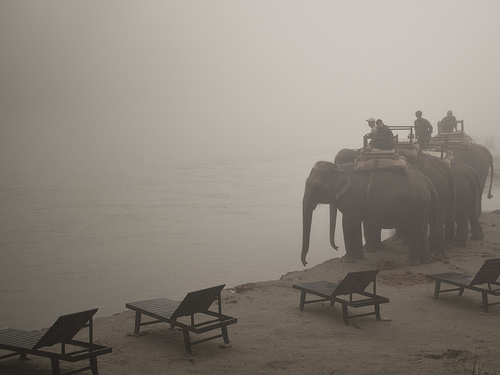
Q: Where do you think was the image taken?
A: It was taken at the beach.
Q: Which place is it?
A: It is a beach.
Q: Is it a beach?
A: Yes, it is a beach.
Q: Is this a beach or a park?
A: It is a beach.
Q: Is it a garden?
A: No, it is a beach.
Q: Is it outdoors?
A: Yes, it is outdoors.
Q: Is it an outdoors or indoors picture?
A: It is outdoors.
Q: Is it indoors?
A: No, it is outdoors.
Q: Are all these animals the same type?
A: Yes, all the animals are elephants.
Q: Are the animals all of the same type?
A: Yes, all the animals are elephants.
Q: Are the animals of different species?
A: No, all the animals are elephants.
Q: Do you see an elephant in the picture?
A: Yes, there is an elephant.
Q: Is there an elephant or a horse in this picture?
A: Yes, there is an elephant.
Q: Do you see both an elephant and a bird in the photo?
A: No, there is an elephant but no birds.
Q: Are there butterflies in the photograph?
A: No, there are no butterflies.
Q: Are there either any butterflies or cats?
A: No, there are no butterflies or cats.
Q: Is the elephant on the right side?
A: Yes, the elephant is on the right of the image.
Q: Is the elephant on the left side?
A: No, the elephant is on the right of the image.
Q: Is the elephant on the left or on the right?
A: The elephant is on the right of the image.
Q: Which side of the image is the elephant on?
A: The elephant is on the right of the image.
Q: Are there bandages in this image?
A: No, there are no bandages.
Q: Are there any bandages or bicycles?
A: No, there are no bandages or bicycles.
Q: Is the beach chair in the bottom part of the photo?
A: Yes, the beach chair is in the bottom of the image.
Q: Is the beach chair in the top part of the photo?
A: No, the beach chair is in the bottom of the image.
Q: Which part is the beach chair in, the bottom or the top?
A: The beach chair is in the bottom of the image.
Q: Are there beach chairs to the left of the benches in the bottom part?
A: Yes, there is a beach chair to the left of the benches.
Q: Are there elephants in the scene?
A: Yes, there is an elephant.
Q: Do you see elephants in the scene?
A: Yes, there is an elephant.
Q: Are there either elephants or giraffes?
A: Yes, there is an elephant.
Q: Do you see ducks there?
A: No, there are no ducks.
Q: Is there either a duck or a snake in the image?
A: No, there are no ducks or snakes.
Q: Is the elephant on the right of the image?
A: Yes, the elephant is on the right of the image.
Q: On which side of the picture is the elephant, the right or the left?
A: The elephant is on the right of the image.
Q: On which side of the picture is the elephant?
A: The elephant is on the right of the image.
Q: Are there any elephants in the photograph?
A: Yes, there is an elephant.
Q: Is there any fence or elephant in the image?
A: Yes, there is an elephant.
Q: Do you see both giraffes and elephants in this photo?
A: No, there is an elephant but no giraffes.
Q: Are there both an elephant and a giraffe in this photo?
A: No, there is an elephant but no giraffes.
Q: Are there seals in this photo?
A: No, there are no seals.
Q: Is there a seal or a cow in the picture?
A: No, there are no seals or cows.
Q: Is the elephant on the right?
A: Yes, the elephant is on the right of the image.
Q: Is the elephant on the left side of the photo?
A: No, the elephant is on the right of the image.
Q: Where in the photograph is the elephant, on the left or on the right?
A: The elephant is on the right of the image.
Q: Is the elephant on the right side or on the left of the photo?
A: The elephant is on the right of the image.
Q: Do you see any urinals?
A: No, there are no urinals.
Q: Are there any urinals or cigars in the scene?
A: No, there are no urinals or cigars.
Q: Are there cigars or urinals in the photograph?
A: No, there are no urinals or cigars.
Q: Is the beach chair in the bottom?
A: Yes, the beach chair is in the bottom of the image.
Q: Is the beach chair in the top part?
A: No, the beach chair is in the bottom of the image.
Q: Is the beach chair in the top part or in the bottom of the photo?
A: The beach chair is in the bottom of the image.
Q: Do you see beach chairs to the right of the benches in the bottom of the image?
A: Yes, there is a beach chair to the right of the benches.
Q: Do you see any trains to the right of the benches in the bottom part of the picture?
A: No, there is a beach chair to the right of the benches.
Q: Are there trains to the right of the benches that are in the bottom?
A: No, there is a beach chair to the right of the benches.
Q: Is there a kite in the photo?
A: No, there are no kites.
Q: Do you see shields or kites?
A: No, there are no kites or shields.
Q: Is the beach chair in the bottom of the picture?
A: Yes, the beach chair is in the bottom of the image.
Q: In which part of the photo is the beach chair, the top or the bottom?
A: The beach chair is in the bottom of the image.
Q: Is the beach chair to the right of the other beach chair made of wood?
A: Yes, the beach chair is made of wood.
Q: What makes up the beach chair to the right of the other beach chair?
A: The beach chair is made of wood.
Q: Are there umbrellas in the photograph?
A: No, there are no umbrellas.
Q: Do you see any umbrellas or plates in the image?
A: No, there are no umbrellas or plates.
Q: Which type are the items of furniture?
A: The pieces of furniture are chairs.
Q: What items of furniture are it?
A: The pieces of furniture are chairs.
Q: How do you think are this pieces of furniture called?
A: These are chairs.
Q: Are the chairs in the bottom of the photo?
A: Yes, the chairs are in the bottom of the image.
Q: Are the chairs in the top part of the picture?
A: No, the chairs are in the bottom of the image.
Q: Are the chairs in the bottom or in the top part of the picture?
A: The chairs are in the bottom of the image.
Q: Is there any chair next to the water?
A: Yes, there are chairs next to the water.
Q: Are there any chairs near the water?
A: Yes, there are chairs near the water.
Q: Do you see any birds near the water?
A: No, there are chairs near the water.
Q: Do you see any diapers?
A: No, there are no diapers.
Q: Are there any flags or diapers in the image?
A: No, there are no diapers or flags.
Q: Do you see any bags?
A: No, there are no bags.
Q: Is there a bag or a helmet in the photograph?
A: No, there are no bags or helmets.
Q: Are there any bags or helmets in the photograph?
A: No, there are no bags or helmets.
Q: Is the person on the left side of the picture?
A: No, the person is on the right of the image.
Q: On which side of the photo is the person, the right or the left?
A: The person is on the right of the image.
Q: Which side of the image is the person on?
A: The person is on the right of the image.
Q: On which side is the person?
A: The person is on the right of the image.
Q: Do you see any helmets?
A: No, there are no helmets.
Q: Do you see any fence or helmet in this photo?
A: No, there are no helmets or fences.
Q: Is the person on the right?
A: Yes, the person is on the right of the image.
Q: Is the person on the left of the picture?
A: No, the person is on the right of the image.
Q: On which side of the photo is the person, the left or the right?
A: The person is on the right of the image.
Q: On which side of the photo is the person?
A: The person is on the right of the image.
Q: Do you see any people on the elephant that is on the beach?
A: Yes, there is a person on the elephant.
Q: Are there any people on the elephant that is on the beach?
A: Yes, there is a person on the elephant.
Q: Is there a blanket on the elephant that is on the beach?
A: No, there is a person on the elephant.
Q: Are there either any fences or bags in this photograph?
A: No, there are no bags or fences.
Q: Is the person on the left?
A: No, the person is on the right of the image.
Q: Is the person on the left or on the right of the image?
A: The person is on the right of the image.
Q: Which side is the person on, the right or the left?
A: The person is on the right of the image.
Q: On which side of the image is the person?
A: The person is on the right of the image.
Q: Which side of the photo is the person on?
A: The person is on the right of the image.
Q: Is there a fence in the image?
A: No, there are no fences.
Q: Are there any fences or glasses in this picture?
A: No, there are no fences or glasses.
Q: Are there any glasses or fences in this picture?
A: No, there are no fences or glasses.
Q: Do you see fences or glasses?
A: No, there are no fences or glasses.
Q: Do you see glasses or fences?
A: No, there are no fences or glasses.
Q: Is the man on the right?
A: Yes, the man is on the right of the image.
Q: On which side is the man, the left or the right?
A: The man is on the right of the image.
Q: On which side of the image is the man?
A: The man is on the right of the image.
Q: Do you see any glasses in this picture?
A: No, there are no glasses.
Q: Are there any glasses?
A: No, there are no glasses.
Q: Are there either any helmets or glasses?
A: No, there are no glasses or helmets.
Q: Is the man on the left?
A: No, the man is on the right of the image.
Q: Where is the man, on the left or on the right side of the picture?
A: The man is on the right of the image.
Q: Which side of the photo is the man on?
A: The man is on the right of the image.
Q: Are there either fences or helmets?
A: No, there are no helmets or fences.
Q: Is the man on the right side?
A: Yes, the man is on the right of the image.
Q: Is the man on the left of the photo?
A: No, the man is on the right of the image.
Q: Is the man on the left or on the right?
A: The man is on the right of the image.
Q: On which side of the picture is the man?
A: The man is on the right of the image.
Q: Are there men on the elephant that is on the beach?
A: Yes, there is a man on the elephant.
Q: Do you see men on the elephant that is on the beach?
A: Yes, there is a man on the elephant.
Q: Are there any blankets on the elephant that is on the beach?
A: No, there is a man on the elephant.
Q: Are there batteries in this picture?
A: No, there are no batteries.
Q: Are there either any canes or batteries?
A: No, there are no batteries or canes.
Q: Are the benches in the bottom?
A: Yes, the benches are in the bottom of the image.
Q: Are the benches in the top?
A: No, the benches are in the bottom of the image.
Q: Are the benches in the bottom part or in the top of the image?
A: The benches are in the bottom of the image.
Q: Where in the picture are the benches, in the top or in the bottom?
A: The benches are in the bottom of the image.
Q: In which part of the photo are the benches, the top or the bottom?
A: The benches are in the bottom of the image.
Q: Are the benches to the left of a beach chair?
A: Yes, the benches are to the left of a beach chair.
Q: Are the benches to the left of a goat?
A: No, the benches are to the left of a beach chair.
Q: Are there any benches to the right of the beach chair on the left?
A: Yes, there are benches to the right of the beach chair.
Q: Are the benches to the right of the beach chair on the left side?
A: Yes, the benches are to the right of the beach chair.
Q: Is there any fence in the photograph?
A: No, there are no fences.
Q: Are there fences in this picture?
A: No, there are no fences.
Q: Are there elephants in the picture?
A: Yes, there is an elephant.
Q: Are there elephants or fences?
A: Yes, there is an elephant.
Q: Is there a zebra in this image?
A: No, there are no zebras.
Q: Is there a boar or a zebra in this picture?
A: No, there are no zebras or boars.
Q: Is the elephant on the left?
A: No, the elephant is on the right of the image.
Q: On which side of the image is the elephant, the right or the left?
A: The elephant is on the right of the image.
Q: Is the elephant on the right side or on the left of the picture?
A: The elephant is on the right of the image.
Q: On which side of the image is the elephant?
A: The elephant is on the right of the image.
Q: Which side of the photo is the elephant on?
A: The elephant is on the right of the image.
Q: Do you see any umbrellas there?
A: No, there are no umbrellas.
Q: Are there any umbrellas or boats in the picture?
A: No, there are no umbrellas or boats.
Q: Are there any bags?
A: No, there are no bags.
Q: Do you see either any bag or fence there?
A: No, there are no bags or fences.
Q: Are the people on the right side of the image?
A: Yes, the people are on the right of the image.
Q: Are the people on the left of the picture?
A: No, the people are on the right of the image.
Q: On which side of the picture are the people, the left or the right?
A: The people are on the right of the image.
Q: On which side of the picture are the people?
A: The people are on the right of the image.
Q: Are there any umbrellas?
A: No, there are no umbrellas.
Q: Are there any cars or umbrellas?
A: No, there are no umbrellas or cars.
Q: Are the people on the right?
A: Yes, the people are on the right of the image.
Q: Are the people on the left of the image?
A: No, the people are on the right of the image.